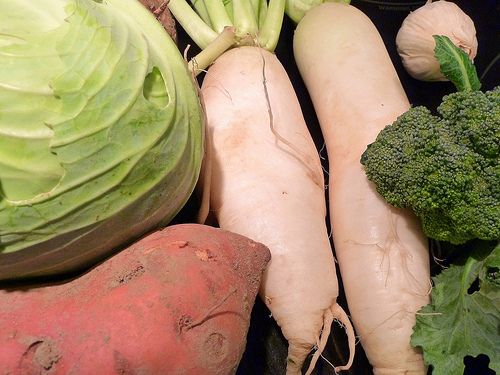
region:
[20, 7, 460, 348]
different vegetables close to each other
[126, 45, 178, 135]
hole in a cabbage leaf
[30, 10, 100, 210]
curved edges of cabbage head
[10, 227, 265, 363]
brown dirt on a sweet potato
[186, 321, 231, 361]
circular marking on a red-skinned vegetable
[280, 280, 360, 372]
thick and thin roots at bottom of turnips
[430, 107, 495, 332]
leaf and florets of broccoli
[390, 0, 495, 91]
leaf covering a head of garlic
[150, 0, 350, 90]
light-green stalks on top of white turnips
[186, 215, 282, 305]
pointy end of a root vegetable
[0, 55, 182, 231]
a cabbage with other vegetables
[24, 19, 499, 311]
a pile of various vegetables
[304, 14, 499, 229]
a black table beneath a pile of vegetables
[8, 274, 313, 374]
a large potato in pile of vetables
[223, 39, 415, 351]
two turnips in a pile of vegetables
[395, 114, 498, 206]
a head of broccoli in a pile of vegetables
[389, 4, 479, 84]
a garlic bulb in a pile of vegetables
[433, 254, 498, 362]
a large broccoli leaf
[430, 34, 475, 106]
a small broccoli leaf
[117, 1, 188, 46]
the corner of a potato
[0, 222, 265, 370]
dirty sweet potato with roots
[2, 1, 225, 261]
green cabbage with bug-eaten leaf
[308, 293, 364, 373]
parsnip root on vegetable end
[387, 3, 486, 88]
garlic under broccoli leaf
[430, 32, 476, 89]
broccoli leaf on top of garlic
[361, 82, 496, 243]
broccoli crown with dirt on it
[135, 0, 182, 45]
brown vegetable behind cabbage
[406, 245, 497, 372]
dry large broccoli leaf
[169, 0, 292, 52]
green leaf stems on parsnip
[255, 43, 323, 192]
root sticking out of parsnip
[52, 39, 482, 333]
a variety of vegetables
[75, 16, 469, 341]
a few healthy foods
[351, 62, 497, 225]
a piece of green broccoli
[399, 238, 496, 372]
a broccoli leaf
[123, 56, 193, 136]
a hole in a leaf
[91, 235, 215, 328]
a dirty vegetable skin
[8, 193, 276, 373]
a red skinned sweet potato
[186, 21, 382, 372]
a pale root vegetable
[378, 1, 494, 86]
a head of garlic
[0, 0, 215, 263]
a head of cabbage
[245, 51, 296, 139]
small black spot on vegetable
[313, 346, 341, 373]
tiny piece of string on vegetable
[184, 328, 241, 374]
small circle in red vegetable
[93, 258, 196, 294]
dirt covered red vegetable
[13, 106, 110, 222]
torn edge of green cabbage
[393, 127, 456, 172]
small spores in broccoli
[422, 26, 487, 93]
single green vegetable leaf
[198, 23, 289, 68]
green end on pink vegetable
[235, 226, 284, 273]
edge of red vegetable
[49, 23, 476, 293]
variety of colorful vegetables